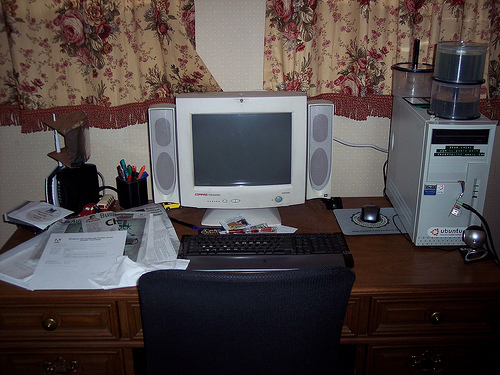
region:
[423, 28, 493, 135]
cds in a case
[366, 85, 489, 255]
white computer tower on the desk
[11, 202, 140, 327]
pile of white papers on the desk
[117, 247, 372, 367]
back of a black chair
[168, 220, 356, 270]
black keyboard on the desk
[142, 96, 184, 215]
white speakers on the computer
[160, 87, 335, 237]
white computer screen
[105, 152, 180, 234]
a cup full of pens and pencils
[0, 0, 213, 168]
brown blanket curtains over the windows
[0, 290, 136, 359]
dark brown desk drawer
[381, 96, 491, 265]
silver computer tower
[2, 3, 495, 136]
tan curtains with red flowers and fringe covering windows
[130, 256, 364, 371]
top of black desk chair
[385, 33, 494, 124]
see through plastic CD cases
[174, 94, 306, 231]
white computer monitor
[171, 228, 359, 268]
black computer keyboard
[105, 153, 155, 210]
black pencil and pen holder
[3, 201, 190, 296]
papers sitting on desk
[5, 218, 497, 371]
brown wood desk with drawers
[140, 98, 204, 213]
computer speaker connected to monitor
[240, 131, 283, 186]
part of a screen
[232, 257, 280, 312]
part of a chair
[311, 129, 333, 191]
part of a speaker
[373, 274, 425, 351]
part of a drawer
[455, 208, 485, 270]
part of a speaker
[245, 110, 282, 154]
part of a monitor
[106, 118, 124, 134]
edge of a curtain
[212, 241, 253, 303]
part of a chair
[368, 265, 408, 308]
edge of a top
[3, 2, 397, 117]
flowered curtains with fringes on the bottom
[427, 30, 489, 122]
discs in round cases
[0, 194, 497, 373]
a dark wood desk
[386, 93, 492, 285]
computer tower on desk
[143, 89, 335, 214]
a white computer monitor with speakers at its sides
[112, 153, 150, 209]
pens in a black container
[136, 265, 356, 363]
a black office chair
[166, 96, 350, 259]
black keyboard in front of monitor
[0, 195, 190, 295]
assorted papers on desk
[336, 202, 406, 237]
silver computer mouse on mouse-pad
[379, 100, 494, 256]
A white computer tower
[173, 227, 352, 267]
A black keyboard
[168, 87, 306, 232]
A white computer monitor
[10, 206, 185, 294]
Assorted papers on a desk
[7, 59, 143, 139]
Fringe on the bottom of curtains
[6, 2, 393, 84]
A flowered pattern on curtains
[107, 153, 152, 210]
A black container holding pens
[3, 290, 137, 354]
A wooden desk drawer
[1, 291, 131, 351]
A brown desk drawer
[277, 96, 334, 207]
A speaker on the side of a computer